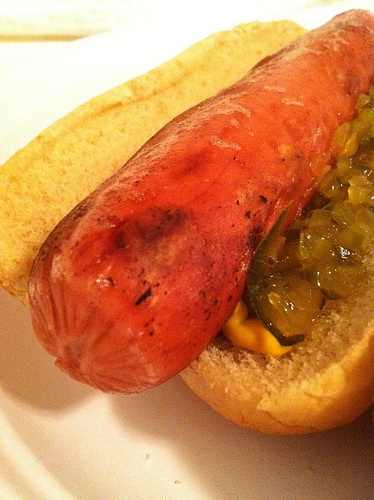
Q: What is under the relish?
A: Mustard.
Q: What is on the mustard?
A: Relish.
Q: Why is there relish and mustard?
A: For flavor.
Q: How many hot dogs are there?
A: One.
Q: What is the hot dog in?
A: Bun.